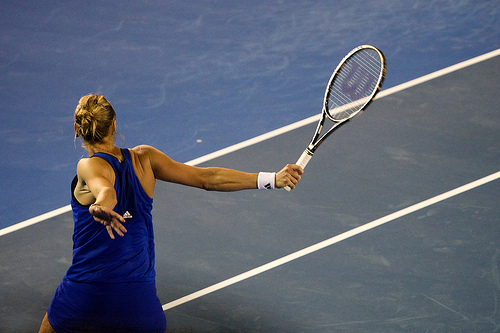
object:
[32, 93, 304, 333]
player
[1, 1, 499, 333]
tennis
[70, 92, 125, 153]
hair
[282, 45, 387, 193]
tennis racket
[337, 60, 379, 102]
w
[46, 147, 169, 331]
outfit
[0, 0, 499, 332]
tennis court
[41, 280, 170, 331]
shorts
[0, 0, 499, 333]
ground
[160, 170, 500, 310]
lines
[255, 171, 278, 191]
wristband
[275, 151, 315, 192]
handle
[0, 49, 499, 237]
lines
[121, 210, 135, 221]
logo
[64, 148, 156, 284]
shirt